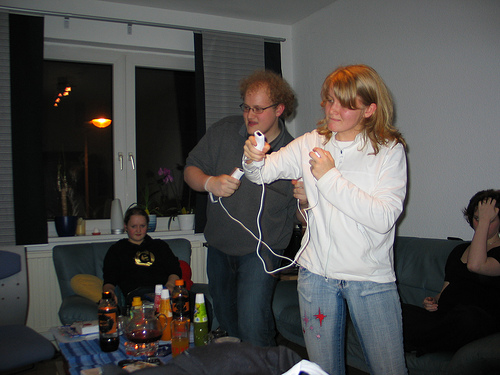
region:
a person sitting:
[100, 192, 180, 301]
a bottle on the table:
[92, 287, 125, 352]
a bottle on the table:
[170, 275, 192, 329]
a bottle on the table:
[161, 290, 172, 332]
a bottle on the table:
[189, 293, 211, 357]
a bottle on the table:
[148, 287, 158, 323]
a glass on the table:
[121, 311, 165, 365]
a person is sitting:
[395, 174, 497, 357]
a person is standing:
[236, 64, 423, 371]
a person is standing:
[190, 62, 301, 349]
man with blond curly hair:
[207, 68, 311, 153]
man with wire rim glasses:
[228, 67, 305, 164]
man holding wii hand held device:
[184, 63, 295, 338]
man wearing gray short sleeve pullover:
[162, 65, 303, 266]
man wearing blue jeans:
[170, 236, 291, 373]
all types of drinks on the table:
[56, 231, 220, 360]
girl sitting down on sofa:
[78, 195, 175, 349]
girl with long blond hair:
[269, 56, 434, 209]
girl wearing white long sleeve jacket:
[232, 66, 437, 302]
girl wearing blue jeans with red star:
[266, 236, 431, 356]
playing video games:
[93, 47, 445, 362]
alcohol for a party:
[86, 259, 230, 359]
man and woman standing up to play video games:
[194, 39, 456, 336]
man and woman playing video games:
[213, 53, 424, 340]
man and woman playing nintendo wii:
[214, 58, 413, 332]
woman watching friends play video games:
[86, 62, 422, 344]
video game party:
[66, 57, 416, 369]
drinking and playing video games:
[87, 60, 367, 372]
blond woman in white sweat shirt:
[302, 55, 414, 365]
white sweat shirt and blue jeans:
[274, 126, 426, 367]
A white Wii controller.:
[205, 122, 280, 167]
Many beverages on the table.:
[103, 288, 200, 348]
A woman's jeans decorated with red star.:
[303, 305, 335, 353]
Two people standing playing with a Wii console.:
[238, 57, 379, 302]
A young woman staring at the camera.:
[111, 207, 166, 272]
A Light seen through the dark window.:
[56, 117, 126, 162]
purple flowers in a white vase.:
[155, 155, 195, 220]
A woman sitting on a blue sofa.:
[70, 240, 185, 322]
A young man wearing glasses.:
[237, 100, 272, 125]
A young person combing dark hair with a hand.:
[465, 190, 496, 255]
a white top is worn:
[256, 127, 405, 275]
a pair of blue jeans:
[297, 260, 407, 372]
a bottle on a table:
[95, 287, 116, 348]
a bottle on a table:
[168, 275, 188, 322]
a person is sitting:
[108, 202, 188, 324]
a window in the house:
[11, 15, 204, 229]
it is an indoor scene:
[2, 1, 498, 367]